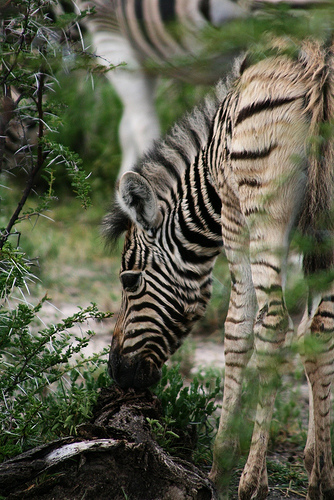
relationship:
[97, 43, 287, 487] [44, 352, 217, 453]
zebra eating grass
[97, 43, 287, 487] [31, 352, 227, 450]
zebra eating grass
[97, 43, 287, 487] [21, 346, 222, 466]
zebra eating grass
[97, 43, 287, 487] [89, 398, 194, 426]
zebra eating grass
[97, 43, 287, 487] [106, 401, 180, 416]
zebra eating grass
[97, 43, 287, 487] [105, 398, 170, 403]
zebra eating grass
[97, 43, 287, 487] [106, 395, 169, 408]
zebra eating grass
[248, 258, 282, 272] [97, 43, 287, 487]
stripe on zebra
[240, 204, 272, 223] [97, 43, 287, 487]
stripe on zebra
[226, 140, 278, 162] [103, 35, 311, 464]
stripe on zebra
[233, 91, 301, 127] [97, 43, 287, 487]
stripe on zebra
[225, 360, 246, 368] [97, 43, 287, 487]
stripe on zebra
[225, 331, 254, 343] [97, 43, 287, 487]
stripe on zebra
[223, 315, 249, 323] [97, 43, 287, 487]
stripe on zebra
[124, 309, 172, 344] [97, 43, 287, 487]
stripe on zebra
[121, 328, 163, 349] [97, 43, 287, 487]
stripe on zebra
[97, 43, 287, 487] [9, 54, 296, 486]
zebra in a forest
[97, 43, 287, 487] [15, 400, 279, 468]
zebra looking down at ground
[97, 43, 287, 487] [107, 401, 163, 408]
zebra smelling something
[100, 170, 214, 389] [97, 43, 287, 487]
head down of a zebra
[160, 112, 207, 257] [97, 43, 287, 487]
neck of a zebra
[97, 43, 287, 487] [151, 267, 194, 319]
zebra with stripes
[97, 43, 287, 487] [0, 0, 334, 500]
zebra in forest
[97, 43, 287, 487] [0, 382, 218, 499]
zebra sniffing grass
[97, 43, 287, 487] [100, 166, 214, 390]
zebra with h head down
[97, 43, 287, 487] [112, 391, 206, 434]
zebra standing beside some plants